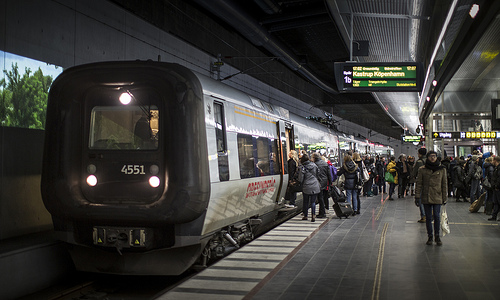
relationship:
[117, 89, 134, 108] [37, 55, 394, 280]
lights on train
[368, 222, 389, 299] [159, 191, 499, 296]
lines on ground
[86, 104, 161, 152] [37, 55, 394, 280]
windshield on train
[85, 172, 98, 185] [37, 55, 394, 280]
light on train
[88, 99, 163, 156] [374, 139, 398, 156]
window on train car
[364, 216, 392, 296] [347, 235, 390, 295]
stripe on ground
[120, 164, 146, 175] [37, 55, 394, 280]
numbers on train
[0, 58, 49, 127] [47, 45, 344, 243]
trees near train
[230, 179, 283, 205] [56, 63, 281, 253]
logo on side of train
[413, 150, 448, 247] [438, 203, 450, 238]
man holding bag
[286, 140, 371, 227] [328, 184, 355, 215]
people with luggage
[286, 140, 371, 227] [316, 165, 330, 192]
people with luggage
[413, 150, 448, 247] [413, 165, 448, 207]
man with coat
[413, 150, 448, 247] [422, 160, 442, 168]
man with scarf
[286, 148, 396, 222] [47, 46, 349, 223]
people on train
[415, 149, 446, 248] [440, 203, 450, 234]
man walking with bag